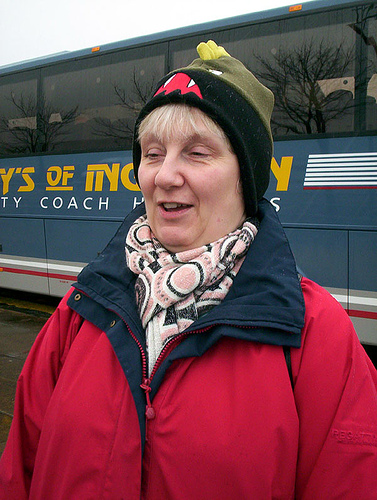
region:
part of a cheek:
[195, 166, 228, 227]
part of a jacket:
[208, 421, 261, 454]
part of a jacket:
[213, 387, 258, 418]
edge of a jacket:
[128, 419, 159, 457]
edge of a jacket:
[290, 467, 305, 498]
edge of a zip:
[130, 426, 152, 489]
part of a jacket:
[209, 447, 251, 478]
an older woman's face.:
[121, 95, 261, 256]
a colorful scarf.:
[99, 202, 279, 377]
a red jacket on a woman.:
[0, 275, 375, 499]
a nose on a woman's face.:
[153, 152, 194, 187]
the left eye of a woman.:
[170, 131, 228, 167]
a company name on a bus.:
[0, 131, 310, 224]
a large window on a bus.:
[172, 8, 362, 156]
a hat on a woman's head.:
[133, 27, 279, 212]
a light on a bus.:
[86, 44, 110, 59]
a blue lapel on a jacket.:
[147, 191, 316, 384]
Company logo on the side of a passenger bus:
[2, 160, 130, 212]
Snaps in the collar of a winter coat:
[72, 291, 83, 301]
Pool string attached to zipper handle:
[137, 378, 160, 422]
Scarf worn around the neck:
[123, 215, 258, 343]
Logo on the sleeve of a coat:
[330, 420, 376, 460]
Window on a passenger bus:
[39, 48, 134, 155]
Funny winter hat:
[125, 34, 270, 202]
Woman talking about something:
[114, 36, 276, 258]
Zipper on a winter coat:
[126, 332, 161, 392]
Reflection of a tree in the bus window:
[257, 38, 355, 129]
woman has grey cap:
[156, 47, 262, 121]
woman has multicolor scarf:
[116, 195, 260, 387]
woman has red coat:
[47, 247, 282, 469]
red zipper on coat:
[123, 348, 153, 426]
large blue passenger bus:
[3, 41, 109, 261]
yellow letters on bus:
[8, 153, 128, 195]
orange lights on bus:
[260, 7, 320, 30]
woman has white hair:
[144, 118, 218, 144]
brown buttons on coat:
[67, 279, 93, 319]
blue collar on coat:
[79, 242, 131, 318]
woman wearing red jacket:
[0, 40, 374, 496]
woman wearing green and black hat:
[1, 51, 372, 494]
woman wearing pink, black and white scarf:
[0, 39, 371, 493]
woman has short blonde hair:
[0, 38, 373, 494]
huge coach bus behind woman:
[0, 0, 373, 291]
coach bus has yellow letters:
[0, 0, 372, 344]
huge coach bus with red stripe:
[0, 0, 370, 287]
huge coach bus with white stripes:
[1, 0, 373, 350]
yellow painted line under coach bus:
[1, 293, 64, 309]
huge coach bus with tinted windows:
[0, 0, 376, 344]